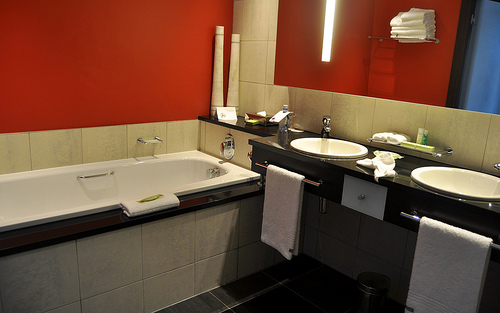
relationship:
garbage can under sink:
[355, 271, 391, 311] [286, 136, 498, 200]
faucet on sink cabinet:
[320, 113, 334, 154] [273, 134, 369, 160]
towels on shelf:
[381, 33, 446, 43] [369, 137, 451, 161]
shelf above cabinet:
[369, 137, 451, 161] [243, 145, 497, 255]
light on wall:
[316, 0, 341, 66] [283, 9, 452, 98]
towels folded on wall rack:
[381, 5, 446, 42] [390, 31, 439, 45]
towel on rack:
[259, 164, 306, 260] [399, 207, 498, 255]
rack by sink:
[399, 207, 498, 255] [286, 125, 366, 161]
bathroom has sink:
[3, 7, 445, 311] [283, 122, 367, 164]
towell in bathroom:
[257, 164, 297, 259] [3, 7, 445, 311]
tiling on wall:
[0, 115, 255, 174] [0, 0, 292, 175]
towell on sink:
[257, 164, 297, 259] [408, 164, 498, 196]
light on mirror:
[292, 0, 361, 86] [271, 14, 483, 88]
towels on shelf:
[381, 33, 446, 43] [358, 28, 445, 48]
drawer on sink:
[331, 165, 400, 223] [297, 123, 377, 181]